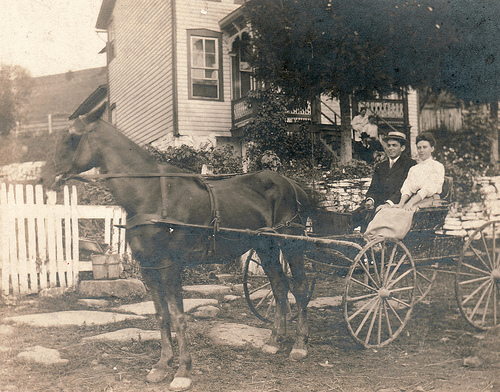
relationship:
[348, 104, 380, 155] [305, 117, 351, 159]
people sitting on steps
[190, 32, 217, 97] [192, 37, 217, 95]
window has curtain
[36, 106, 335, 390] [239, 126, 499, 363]
horse drawing carriage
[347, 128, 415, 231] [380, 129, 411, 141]
man wearing hat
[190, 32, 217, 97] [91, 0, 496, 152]
window on house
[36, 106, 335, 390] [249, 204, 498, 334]
horse on carriage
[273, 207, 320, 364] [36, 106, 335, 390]
leg of horse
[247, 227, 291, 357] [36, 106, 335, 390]
leg of horse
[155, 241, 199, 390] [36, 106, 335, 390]
leg of horse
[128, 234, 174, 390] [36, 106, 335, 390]
leg of horse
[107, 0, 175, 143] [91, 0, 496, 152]
side of house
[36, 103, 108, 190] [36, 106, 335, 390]
head of horse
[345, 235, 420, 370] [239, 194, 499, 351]
wheel below cart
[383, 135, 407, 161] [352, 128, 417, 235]
head on man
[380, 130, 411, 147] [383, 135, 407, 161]
hat on head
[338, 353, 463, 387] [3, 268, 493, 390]
dirt on ground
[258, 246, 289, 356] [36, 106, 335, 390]
leg of horse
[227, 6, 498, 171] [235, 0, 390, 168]
tree on tree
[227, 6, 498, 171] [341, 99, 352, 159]
tree has trunk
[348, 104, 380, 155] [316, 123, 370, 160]
people sitting on step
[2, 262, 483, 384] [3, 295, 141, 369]
dirt yard with some rocks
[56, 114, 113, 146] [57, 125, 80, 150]
blinders over eyes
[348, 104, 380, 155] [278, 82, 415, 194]
people standing on stairs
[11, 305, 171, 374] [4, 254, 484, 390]
rocks on ground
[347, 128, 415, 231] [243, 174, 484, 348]
man sitting in carriage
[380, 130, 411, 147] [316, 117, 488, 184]
hat on mans head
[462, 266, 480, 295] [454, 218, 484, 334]
spokes of wheel